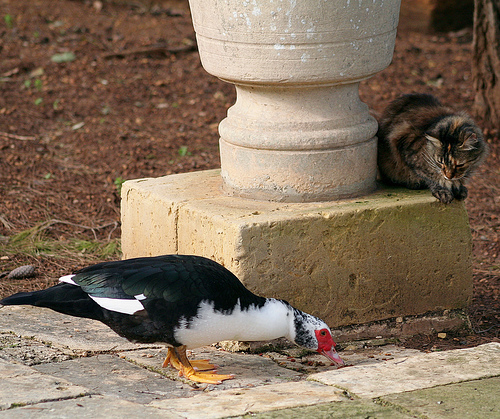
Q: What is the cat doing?
A: Watching the bird.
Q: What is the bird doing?
A: Looking for food.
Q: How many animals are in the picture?
A: Two.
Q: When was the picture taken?
A: During the day.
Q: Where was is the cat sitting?
A: On a cinder block.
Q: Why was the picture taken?
A: To capture the cat watching the bird.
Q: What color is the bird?
A: Black, white and red.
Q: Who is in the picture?
A: A cat and bird.